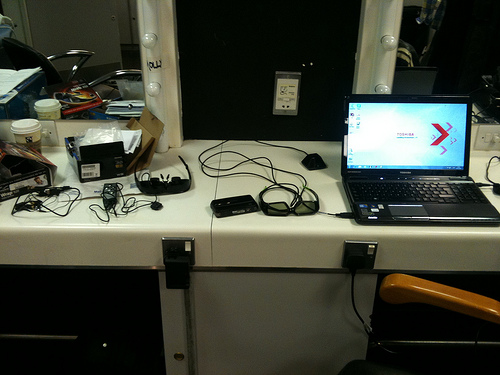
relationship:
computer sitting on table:
[341, 93, 500, 228] [4, 119, 496, 373]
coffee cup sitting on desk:
[10, 118, 43, 152] [2, 129, 499, 374]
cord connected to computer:
[196, 126, 335, 217] [341, 93, 500, 228]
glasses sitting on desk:
[132, 151, 193, 193] [2, 129, 499, 374]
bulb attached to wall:
[146, 82, 162, 97] [136, 0, 498, 146]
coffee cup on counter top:
[8, 117, 43, 152] [0, 138, 498, 271]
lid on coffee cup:
[8, 116, 39, 133] [11, 115, 51, 153]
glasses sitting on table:
[134, 154, 192, 195] [12, 132, 497, 279]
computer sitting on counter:
[341, 93, 500, 228] [7, 139, 499, 273]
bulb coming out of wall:
[142, 33, 157, 49] [132, 0, 404, 154]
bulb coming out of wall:
[146, 82, 162, 97] [132, 0, 404, 154]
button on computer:
[357, 186, 359, 191] [342, 91, 496, 218]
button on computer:
[367, 185, 373, 188] [342, 91, 496, 218]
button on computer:
[389, 184, 397, 186] [342, 91, 496, 218]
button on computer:
[410, 186, 420, 191] [342, 91, 496, 218]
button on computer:
[433, 185, 449, 197] [342, 91, 496, 218]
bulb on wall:
[135, 27, 161, 51] [132, 0, 404, 154]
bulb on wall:
[146, 82, 162, 97] [132, 0, 404, 154]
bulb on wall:
[371, 29, 399, 54] [132, 0, 404, 154]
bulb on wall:
[368, 75, 391, 93] [132, 0, 404, 154]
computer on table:
[341, 93, 500, 228] [34, 80, 477, 310]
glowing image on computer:
[349, 105, 466, 170] [341, 93, 500, 228]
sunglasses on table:
[257, 186, 319, 216] [4, 119, 496, 373]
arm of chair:
[378, 269, 497, 321] [369, 260, 499, 338]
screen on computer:
[345, 104, 470, 168] [341, 93, 500, 228]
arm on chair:
[378, 271, 497, 320] [333, 266, 494, 371]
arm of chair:
[378, 269, 497, 321] [349, 223, 485, 337]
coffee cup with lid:
[10, 118, 43, 152] [11, 117, 40, 135]